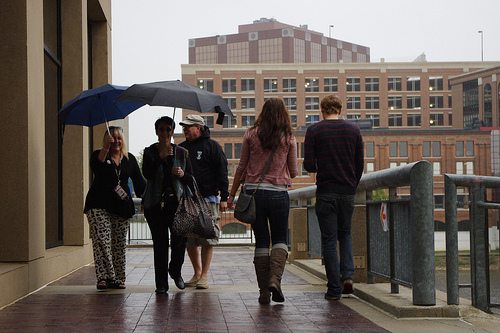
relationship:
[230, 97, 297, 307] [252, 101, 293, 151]
woman has hair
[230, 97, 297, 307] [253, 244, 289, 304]
woman has boots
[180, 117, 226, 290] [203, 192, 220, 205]
man has shirt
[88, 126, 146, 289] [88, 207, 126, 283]
woman has pants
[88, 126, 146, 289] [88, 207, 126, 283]
woman with pants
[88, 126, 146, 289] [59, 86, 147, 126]
woman holding umbrella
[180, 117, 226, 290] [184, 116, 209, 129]
man in grey cap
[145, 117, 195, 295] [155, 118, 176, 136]
woman with short hair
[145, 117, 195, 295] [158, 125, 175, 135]
woman with glasses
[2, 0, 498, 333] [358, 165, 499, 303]
scene has railing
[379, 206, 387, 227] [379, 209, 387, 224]
arrow has arrow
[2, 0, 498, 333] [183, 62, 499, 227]
scene shows building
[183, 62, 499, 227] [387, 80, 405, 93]
building shows a window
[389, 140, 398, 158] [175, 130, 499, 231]
window belongs in building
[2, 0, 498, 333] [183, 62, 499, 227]
scene show window in a building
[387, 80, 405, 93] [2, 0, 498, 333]
window in building in scene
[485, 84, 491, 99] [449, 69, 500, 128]
window on a corner building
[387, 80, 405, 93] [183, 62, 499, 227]
window adorns building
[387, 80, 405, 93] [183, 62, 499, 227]
window in row on building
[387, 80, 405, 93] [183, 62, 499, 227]
window in window row on building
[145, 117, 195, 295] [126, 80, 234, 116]
lady holding black umbrella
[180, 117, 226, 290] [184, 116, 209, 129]
man has cap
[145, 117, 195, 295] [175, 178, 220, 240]
lady has bag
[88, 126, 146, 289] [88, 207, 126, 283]
lady has pants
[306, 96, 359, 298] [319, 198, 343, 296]
person has leg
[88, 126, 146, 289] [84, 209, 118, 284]
person possesses leg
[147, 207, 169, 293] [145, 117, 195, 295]
leg belongs to a person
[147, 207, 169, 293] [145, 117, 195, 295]
leg under wat of a person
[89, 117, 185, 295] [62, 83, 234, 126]
two people are holding onto umbrellas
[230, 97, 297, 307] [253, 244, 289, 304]
girl with knee high boots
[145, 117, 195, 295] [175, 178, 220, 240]
girl has dark colored purse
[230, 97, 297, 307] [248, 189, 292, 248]
girl wearing blue jeans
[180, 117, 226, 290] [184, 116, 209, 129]
man wearing ball cap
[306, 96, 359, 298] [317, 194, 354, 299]
man walking in blue jeans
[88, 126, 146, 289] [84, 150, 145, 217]
blonde woman in black shirt